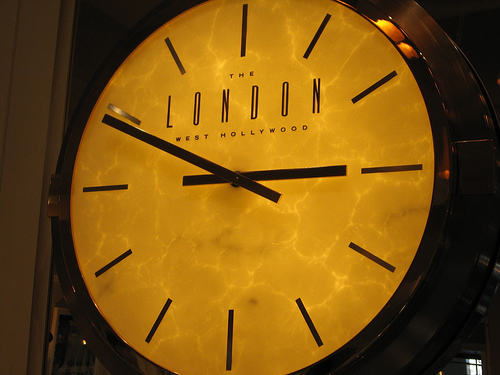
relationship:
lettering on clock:
[163, 76, 321, 130] [70, 23, 436, 374]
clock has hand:
[70, 23, 436, 374] [182, 165, 347, 186]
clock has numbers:
[70, 23, 436, 374] [332, 58, 439, 328]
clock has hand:
[70, 23, 436, 374] [139, 150, 324, 200]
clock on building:
[70, 23, 436, 374] [2, 4, 497, 371]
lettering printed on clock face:
[163, 76, 321, 130] [66, 0, 436, 375]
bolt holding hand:
[204, 167, 264, 197] [182, 165, 347, 186]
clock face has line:
[72, 1, 448, 374] [239, 4, 246, 55]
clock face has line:
[72, 1, 448, 374] [352, 71, 394, 103]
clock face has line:
[72, 1, 448, 374] [347, 241, 394, 271]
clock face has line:
[72, 1, 448, 374] [226, 308, 233, 369]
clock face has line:
[72, 1, 448, 374] [295, 297, 324, 348]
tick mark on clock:
[349, 240, 395, 275] [43, 0, 498, 373]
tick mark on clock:
[358, 163, 428, 173] [43, 0, 498, 373]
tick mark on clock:
[352, 67, 393, 102] [43, 0, 498, 373]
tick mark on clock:
[303, 16, 336, 58] [43, 0, 498, 373]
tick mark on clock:
[243, 5, 246, 58] [43, 0, 498, 373]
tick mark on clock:
[139, 292, 174, 347] [70, 23, 436, 374]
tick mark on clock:
[94, 243, 134, 278] [70, 23, 436, 374]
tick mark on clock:
[359, 158, 424, 173] [70, 23, 436, 374]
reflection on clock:
[289, 17, 449, 350] [83, 25, 473, 345]